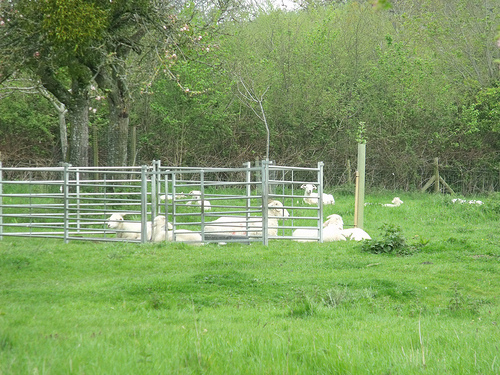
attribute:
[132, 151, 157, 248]
pole — silver, wooden, fence's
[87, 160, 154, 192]
fence pole — silver, wooden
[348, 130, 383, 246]
fence pole — silver, wooden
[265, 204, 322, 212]
fence pole — silver, wooden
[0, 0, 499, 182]
trees — thicket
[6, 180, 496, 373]
field — grassy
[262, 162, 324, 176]
fence pole — silver, wooden, fence's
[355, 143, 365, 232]
metal pole — green metal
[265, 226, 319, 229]
pole — silver, wooden, fence's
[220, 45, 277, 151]
tree — small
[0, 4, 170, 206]
trees — big, flowered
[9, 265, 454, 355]
grass — lush, green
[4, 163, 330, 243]
pen — metal